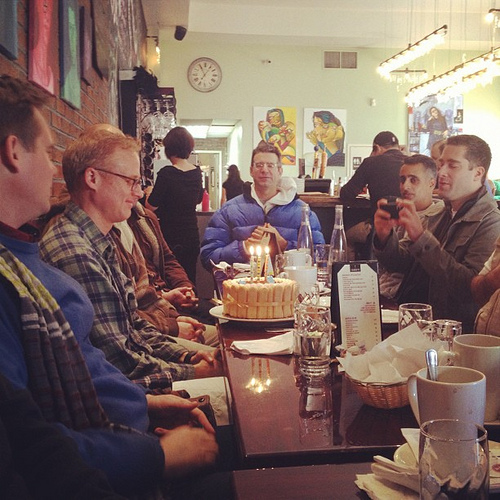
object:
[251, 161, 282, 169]
eyeglasses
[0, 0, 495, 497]
photo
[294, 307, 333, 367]
cup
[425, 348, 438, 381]
spoon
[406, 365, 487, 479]
cup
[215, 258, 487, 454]
table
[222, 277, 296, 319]
cake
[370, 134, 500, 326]
person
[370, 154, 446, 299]
person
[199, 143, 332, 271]
person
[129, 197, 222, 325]
person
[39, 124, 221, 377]
person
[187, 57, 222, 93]
clock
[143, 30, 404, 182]
wall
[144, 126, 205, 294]
woman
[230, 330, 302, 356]
serviette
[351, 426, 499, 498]
serviette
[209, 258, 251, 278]
serviette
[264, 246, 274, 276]
candle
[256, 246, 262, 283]
candle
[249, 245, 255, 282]
candle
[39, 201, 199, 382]
shirt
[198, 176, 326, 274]
coat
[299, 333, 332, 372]
liquid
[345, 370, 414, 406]
basket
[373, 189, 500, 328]
coat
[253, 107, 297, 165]
art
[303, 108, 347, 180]
art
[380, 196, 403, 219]
camera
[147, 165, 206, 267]
dress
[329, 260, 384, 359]
menu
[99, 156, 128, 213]
skin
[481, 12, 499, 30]
lights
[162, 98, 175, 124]
glasses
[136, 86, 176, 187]
bar